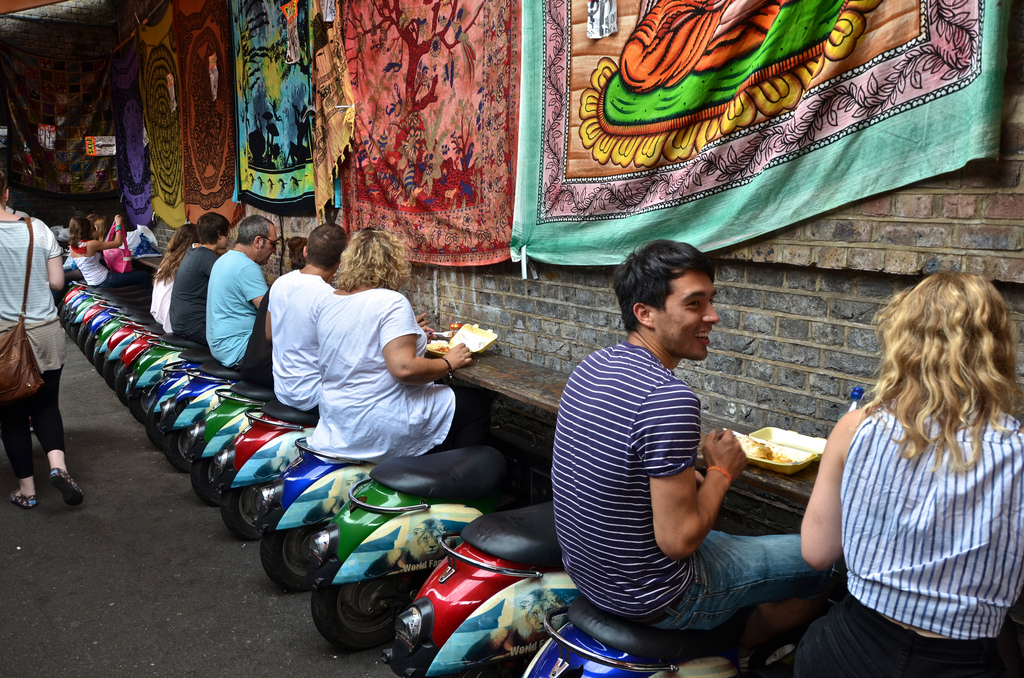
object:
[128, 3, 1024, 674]
wall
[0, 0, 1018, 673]
building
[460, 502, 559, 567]
seat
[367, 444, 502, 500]
seat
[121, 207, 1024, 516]
counter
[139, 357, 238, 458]
motorcycle seat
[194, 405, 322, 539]
motorcycle seat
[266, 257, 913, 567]
counter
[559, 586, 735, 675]
bike seat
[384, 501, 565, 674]
bike seat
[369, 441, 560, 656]
bike seat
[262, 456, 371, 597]
bike seat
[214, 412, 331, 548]
bike seat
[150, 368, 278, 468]
bike seat